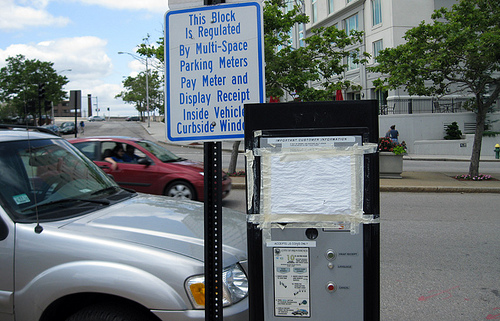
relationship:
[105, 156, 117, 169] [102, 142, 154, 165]
arm hanging out of window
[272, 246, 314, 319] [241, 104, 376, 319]
instructions on parking meter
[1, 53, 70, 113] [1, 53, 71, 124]
leaves on tree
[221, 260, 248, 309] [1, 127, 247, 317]
headlight on car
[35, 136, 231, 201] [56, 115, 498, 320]
car driving down road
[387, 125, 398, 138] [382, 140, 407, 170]
person walking behind plant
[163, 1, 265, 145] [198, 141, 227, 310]
sign attached to black pole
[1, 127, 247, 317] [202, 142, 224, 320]
car parked near black pole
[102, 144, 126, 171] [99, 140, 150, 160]
person wearing shirt